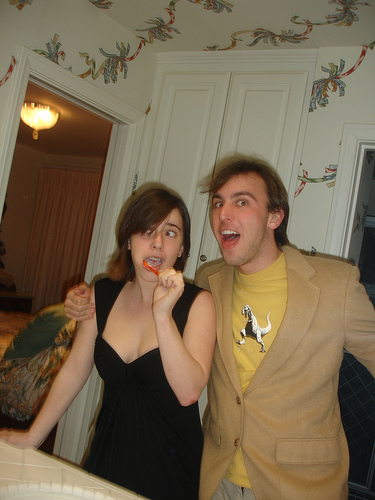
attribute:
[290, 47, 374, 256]
wall — patterned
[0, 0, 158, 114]
wall — patterned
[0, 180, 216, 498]
woman — brushing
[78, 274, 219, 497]
dress — black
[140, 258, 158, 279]
toothbrush — orange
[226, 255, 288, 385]
shirt — yellow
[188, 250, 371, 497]
suit — brown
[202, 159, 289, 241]
hair — brown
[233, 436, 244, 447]
button — orange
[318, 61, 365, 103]
wall — white